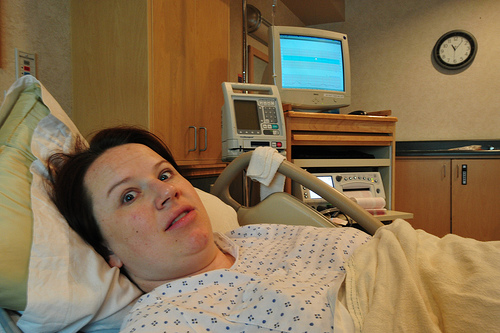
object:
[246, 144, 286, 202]
cloth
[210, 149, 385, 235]
bar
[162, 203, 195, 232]
mouth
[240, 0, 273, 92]
rail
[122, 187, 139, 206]
eye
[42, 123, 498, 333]
person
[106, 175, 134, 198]
eyebrow